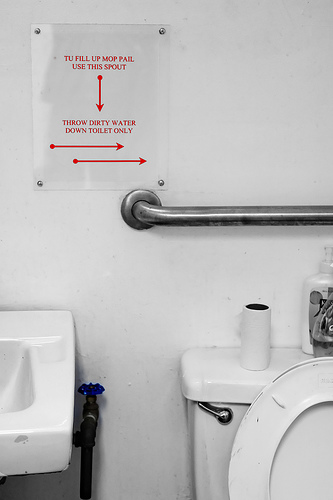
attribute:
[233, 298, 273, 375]
roll — white, small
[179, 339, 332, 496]
toilet — white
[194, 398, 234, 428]
flusher — silver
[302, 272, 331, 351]
bottle — white, lotion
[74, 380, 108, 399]
handle — blue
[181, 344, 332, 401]
lid — white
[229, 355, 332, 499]
seat — up, white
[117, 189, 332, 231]
bar — silver, metal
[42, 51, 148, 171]
instructions — red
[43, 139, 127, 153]
arrow — pointing, red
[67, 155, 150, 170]
arrow — pointing, red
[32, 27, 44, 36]
bolt — metal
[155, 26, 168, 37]
bolt — metal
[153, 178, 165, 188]
bolt — metal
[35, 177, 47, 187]
bolt — metal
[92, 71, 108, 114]
arrow — pointing, red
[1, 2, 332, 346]
wall — white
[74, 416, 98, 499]
pipe — black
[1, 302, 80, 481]
sink — white, chipped